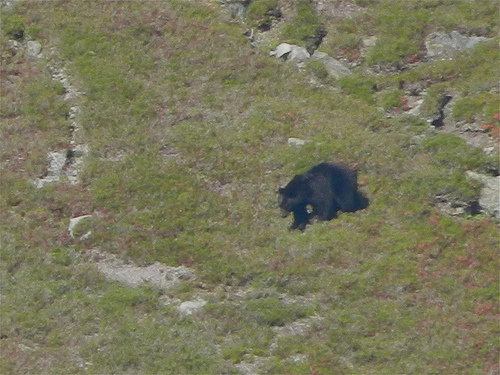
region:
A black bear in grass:
[255, 159, 375, 237]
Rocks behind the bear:
[260, 38, 365, 83]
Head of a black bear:
[271, 187, 303, 225]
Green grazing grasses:
[96, 58, 225, 159]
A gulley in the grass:
[276, 49, 475, 115]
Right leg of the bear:
[285, 213, 313, 240]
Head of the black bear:
[258, 186, 304, 222]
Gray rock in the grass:
[50, 205, 112, 247]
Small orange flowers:
[479, 112, 499, 146]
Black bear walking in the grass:
[250, 130, 406, 242]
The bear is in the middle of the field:
[234, 139, 385, 239]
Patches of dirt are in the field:
[100, 245, 242, 307]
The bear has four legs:
[246, 148, 376, 217]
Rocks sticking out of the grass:
[270, 40, 483, 120]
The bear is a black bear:
[268, 175, 383, 239]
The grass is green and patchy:
[132, 154, 208, 216]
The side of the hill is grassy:
[64, 27, 231, 127]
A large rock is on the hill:
[260, 38, 362, 79]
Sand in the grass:
[77, 248, 170, 300]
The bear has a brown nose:
[259, 185, 310, 230]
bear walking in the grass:
[267, 143, 382, 240]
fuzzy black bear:
[255, 143, 390, 243]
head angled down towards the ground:
[264, 186, 299, 221]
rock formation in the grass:
[260, 37, 358, 95]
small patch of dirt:
[97, 257, 192, 295]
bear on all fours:
[257, 155, 383, 241]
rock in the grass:
[267, 36, 303, 65]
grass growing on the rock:
[422, 77, 449, 120]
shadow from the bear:
[359, 190, 368, 210]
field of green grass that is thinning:
[4, 2, 499, 362]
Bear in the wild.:
[219, 139, 451, 252]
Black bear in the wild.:
[259, 105, 385, 271]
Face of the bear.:
[251, 167, 303, 227]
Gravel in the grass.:
[70, 176, 249, 328]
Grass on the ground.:
[19, 100, 231, 275]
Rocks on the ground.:
[263, 22, 412, 134]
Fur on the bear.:
[252, 108, 394, 245]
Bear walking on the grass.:
[262, 135, 411, 250]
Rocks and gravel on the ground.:
[34, 124, 226, 372]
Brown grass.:
[325, 27, 387, 94]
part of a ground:
[156, 140, 243, 245]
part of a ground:
[296, 264, 357, 338]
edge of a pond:
[316, 192, 352, 217]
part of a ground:
[381, 151, 433, 236]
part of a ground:
[414, 178, 456, 249]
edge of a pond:
[325, 205, 356, 222]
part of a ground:
[228, 285, 262, 319]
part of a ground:
[194, 292, 254, 359]